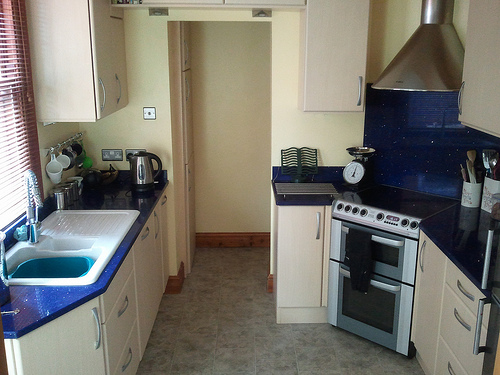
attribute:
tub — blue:
[14, 251, 97, 293]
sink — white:
[4, 196, 139, 302]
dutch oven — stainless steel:
[328, 182, 462, 357]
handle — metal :
[85, 299, 125, 361]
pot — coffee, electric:
[125, 150, 162, 187]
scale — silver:
[342, 146, 375, 186]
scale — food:
[337, 140, 379, 193]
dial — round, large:
[342, 141, 379, 161]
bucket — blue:
[11, 250, 108, 283]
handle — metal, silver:
[314, 208, 320, 239]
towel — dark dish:
[346, 222, 373, 297]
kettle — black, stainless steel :
[124, 143, 177, 197]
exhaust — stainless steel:
[370, 17, 476, 95]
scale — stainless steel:
[341, 147, 373, 187]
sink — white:
[39, 227, 89, 257]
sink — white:
[2, 205, 144, 292]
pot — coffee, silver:
[128, 152, 169, 195]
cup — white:
[57, 141, 73, 171]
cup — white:
[40, 146, 68, 185]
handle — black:
[142, 150, 165, 182]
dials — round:
[335, 202, 418, 237]